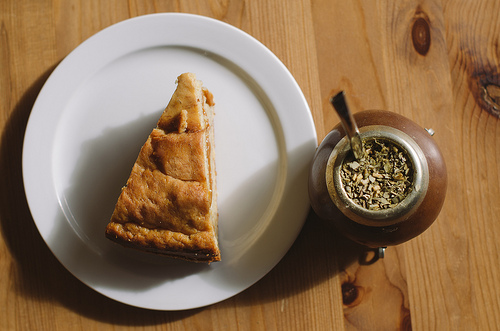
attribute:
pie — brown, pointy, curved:
[83, 59, 224, 265]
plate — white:
[22, 12, 320, 291]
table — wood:
[12, 6, 500, 328]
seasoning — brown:
[368, 156, 392, 173]